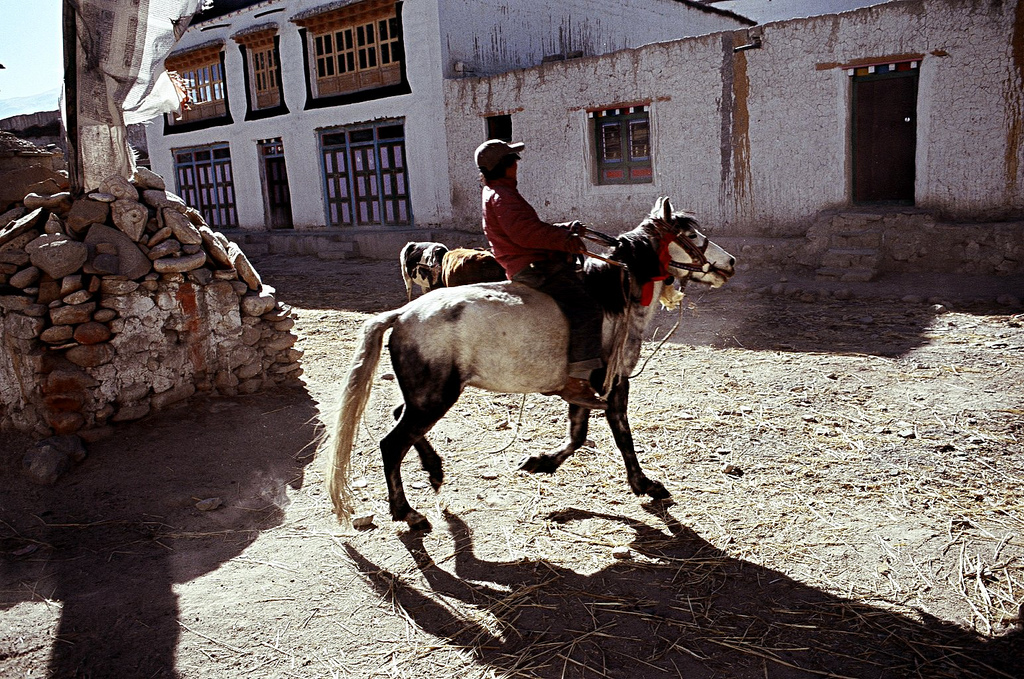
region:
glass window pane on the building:
[375, 17, 401, 65]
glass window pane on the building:
[345, 20, 377, 69]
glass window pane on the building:
[329, 21, 353, 72]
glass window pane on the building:
[311, 27, 334, 82]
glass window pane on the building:
[264, 65, 280, 91]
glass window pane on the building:
[257, 43, 278, 67]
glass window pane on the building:
[241, 43, 262, 75]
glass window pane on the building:
[247, 65, 263, 88]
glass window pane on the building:
[200, 62, 219, 100]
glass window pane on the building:
[174, 66, 201, 106]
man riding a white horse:
[309, 127, 749, 565]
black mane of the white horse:
[604, 200, 696, 302]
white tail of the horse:
[329, 322, 386, 525]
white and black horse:
[319, 206, 735, 555]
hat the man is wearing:
[468, 134, 522, 169]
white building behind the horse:
[146, 1, 1019, 246]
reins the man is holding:
[563, 207, 687, 274]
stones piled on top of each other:
[3, 172, 307, 429]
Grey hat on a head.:
[474, 134, 525, 176]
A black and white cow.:
[393, 241, 448, 296]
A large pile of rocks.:
[1, 179, 309, 437]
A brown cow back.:
[441, 250, 506, 290]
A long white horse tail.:
[329, 311, 397, 528]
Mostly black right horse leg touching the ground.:
[610, 372, 671, 505]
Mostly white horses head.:
[654, 210, 740, 296]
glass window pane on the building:
[370, 11, 400, 59]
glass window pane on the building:
[327, 30, 357, 73]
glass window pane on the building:
[307, 27, 334, 78]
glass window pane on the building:
[261, 36, 281, 90]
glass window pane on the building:
[245, 46, 265, 89]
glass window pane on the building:
[204, 52, 218, 98]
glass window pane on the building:
[599, 112, 619, 164]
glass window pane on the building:
[621, 118, 648, 160]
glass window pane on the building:
[172, 64, 198, 115]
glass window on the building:
[593, 115, 620, 160]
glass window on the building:
[629, 112, 645, 157]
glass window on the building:
[374, 14, 400, 60]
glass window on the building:
[348, 20, 377, 63]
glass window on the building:
[310, 30, 336, 75]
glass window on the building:
[247, 43, 264, 69]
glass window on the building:
[250, 69, 264, 93]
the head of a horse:
[623, 177, 748, 320]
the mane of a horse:
[590, 218, 677, 261]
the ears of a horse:
[646, 174, 695, 238]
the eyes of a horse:
[655, 212, 710, 250]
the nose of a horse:
[708, 244, 743, 276]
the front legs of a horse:
[558, 382, 666, 545]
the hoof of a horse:
[637, 476, 698, 516]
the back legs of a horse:
[351, 385, 453, 531]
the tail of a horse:
[310, 323, 400, 492]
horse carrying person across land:
[311, 189, 758, 557]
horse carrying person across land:
[314, 187, 755, 536]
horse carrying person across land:
[299, 192, 743, 550]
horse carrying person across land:
[316, 187, 778, 555]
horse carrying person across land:
[318, 187, 775, 539]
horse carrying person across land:
[318, 193, 762, 539]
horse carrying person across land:
[322, 189, 766, 538]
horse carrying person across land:
[302, 170, 755, 532]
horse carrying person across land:
[314, 187, 798, 539]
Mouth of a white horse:
[704, 255, 742, 290]